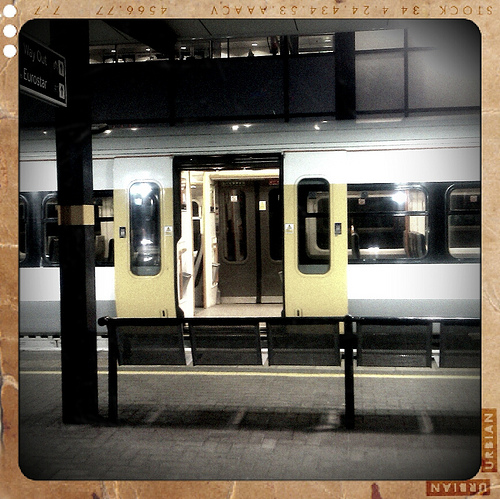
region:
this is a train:
[146, 137, 468, 296]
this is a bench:
[107, 308, 474, 372]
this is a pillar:
[48, 140, 103, 443]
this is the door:
[187, 180, 269, 282]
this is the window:
[358, 193, 408, 240]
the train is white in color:
[378, 269, 432, 288]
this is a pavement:
[158, 397, 294, 469]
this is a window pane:
[133, 187, 155, 257]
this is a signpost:
[25, 42, 72, 99]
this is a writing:
[21, 65, 53, 90]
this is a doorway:
[164, 182, 299, 325]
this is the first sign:
[105, 314, 202, 380]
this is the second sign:
[195, 297, 270, 387]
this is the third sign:
[260, 301, 350, 378]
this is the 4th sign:
[345, 307, 436, 376]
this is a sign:
[436, 308, 486, 364]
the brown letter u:
[482, 455, 499, 473]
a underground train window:
[336, 177, 436, 284]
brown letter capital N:
[483, 407, 495, 425]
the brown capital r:
[483, 449, 498, 460]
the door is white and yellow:
[110, 157, 175, 317]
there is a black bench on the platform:
[101, 316, 480, 425]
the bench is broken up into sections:
[103, 318, 186, 366]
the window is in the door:
[291, 178, 330, 276]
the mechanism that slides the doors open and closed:
[172, 150, 282, 162]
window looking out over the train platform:
[214, 37, 287, 59]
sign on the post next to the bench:
[25, 40, 67, 102]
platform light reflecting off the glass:
[386, 193, 411, 209]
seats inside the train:
[398, 227, 426, 259]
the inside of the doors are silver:
[217, 182, 285, 304]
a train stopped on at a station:
[27, 130, 479, 318]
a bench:
[108, 320, 473, 418]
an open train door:
[170, 160, 287, 312]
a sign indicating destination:
[14, 41, 72, 108]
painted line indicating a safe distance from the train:
[26, 352, 489, 392]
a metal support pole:
[55, 30, 106, 406]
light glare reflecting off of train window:
[372, 173, 428, 235]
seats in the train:
[403, 228, 428, 259]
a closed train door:
[222, 192, 275, 300]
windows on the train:
[328, 190, 485, 260]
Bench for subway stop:
[103, 310, 498, 375]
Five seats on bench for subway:
[95, 301, 497, 394]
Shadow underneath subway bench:
[85, 386, 498, 450]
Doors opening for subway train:
[83, 113, 366, 340]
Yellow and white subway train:
[14, 92, 489, 340]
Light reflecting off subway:
[105, 154, 180, 229]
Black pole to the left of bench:
[14, 25, 111, 440]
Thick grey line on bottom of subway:
[10, 290, 481, 341]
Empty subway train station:
[19, 24, 480, 479]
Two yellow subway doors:
[77, 131, 392, 369]